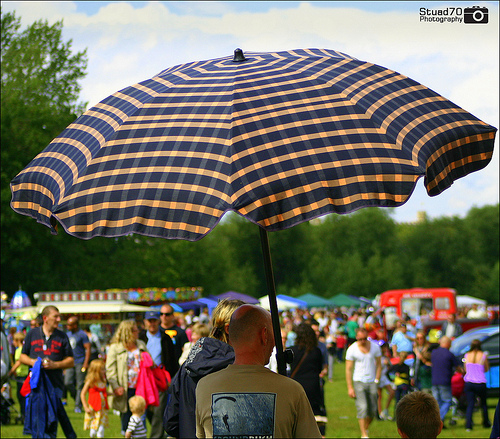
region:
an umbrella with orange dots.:
[4, 35, 494, 250]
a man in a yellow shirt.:
[166, 287, 327, 435]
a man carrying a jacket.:
[1, 294, 76, 429]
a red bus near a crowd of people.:
[363, 272, 464, 341]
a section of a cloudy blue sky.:
[127, 21, 169, 31]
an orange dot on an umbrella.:
[284, 187, 296, 199]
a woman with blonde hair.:
[104, 320, 155, 413]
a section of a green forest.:
[460, 202, 498, 294]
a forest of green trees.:
[0, 5, 102, 225]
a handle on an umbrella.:
[243, 214, 300, 385]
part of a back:
[259, 384, 271, 399]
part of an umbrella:
[281, 347, 306, 367]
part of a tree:
[369, 220, 395, 253]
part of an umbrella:
[256, 210, 288, 270]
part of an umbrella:
[188, 176, 202, 203]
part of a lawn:
[333, 387, 340, 412]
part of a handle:
[273, 322, 301, 335]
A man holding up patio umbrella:
[5, 41, 499, 418]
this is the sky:
[187, 7, 241, 33]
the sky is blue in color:
[86, 4, 106, 16]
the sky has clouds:
[98, 14, 155, 64]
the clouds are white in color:
[105, 14, 142, 57]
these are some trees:
[365, 212, 492, 279]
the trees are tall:
[347, 214, 373, 284]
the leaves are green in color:
[324, 220, 388, 270]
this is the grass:
[331, 397, 353, 429]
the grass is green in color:
[335, 399, 349, 435]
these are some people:
[27, 294, 498, 436]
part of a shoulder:
[289, 371, 302, 401]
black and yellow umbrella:
[119, 33, 380, 255]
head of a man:
[195, 285, 292, 387]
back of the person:
[180, 365, 284, 437]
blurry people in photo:
[313, 280, 453, 387]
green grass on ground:
[327, 394, 354, 429]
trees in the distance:
[292, 205, 464, 304]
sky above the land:
[78, 4, 205, 70]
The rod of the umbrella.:
[257, 226, 294, 376]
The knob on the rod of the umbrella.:
[282, 346, 294, 363]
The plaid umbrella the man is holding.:
[0, 49, 499, 219]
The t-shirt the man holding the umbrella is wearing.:
[198, 365, 308, 437]